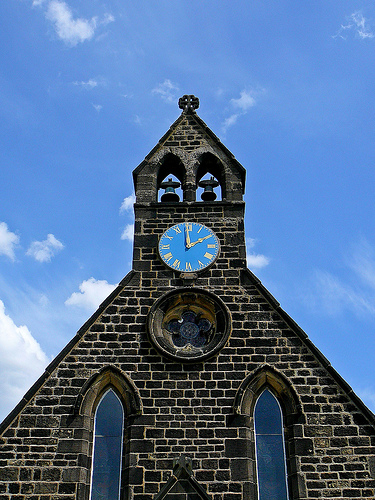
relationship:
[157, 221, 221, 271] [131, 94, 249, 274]
clock on tower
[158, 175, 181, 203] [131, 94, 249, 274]
bell on tower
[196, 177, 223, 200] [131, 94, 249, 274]
bell on tower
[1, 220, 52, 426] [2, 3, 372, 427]
cloud in sky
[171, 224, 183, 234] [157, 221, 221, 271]
roman numeral on clock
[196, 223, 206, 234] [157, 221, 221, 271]
roman numeral on clock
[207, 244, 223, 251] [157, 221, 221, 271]
roman numeral on clock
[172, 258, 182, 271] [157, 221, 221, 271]
roman numeral on clock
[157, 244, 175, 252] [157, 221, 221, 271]
roman numeral on clock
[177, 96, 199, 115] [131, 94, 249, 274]
steeple of tower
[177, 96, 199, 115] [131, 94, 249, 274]
steeple on tower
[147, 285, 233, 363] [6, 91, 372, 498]
decoration on building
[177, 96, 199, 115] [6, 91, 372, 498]
steeple on top of building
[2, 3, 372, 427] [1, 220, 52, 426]
sky has cloud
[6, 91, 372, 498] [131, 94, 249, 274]
building has tower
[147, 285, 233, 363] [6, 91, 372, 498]
design on building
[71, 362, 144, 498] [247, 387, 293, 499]
brick around window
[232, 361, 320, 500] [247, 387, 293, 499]
brick around window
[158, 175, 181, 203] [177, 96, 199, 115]
bell in steeple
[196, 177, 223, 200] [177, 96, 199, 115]
bell in steeple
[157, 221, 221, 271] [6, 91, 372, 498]
clock on front of building